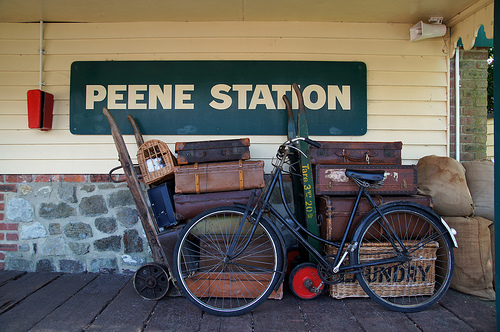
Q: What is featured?
A: A bicycle.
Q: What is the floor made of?
A: Wood.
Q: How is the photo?
A: Clear.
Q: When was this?
A: Daytime.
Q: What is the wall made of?
A: Bricks.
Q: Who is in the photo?
A: No one.